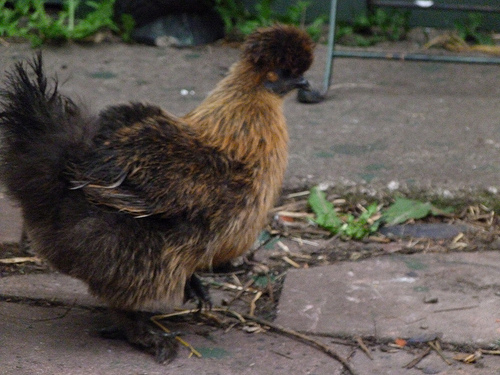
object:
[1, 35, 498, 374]
ground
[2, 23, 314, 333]
chicken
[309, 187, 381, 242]
leaf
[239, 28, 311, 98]
head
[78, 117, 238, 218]
wing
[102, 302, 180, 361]
foot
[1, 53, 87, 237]
tail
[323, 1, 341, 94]
pole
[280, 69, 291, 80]
eye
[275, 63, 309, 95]
face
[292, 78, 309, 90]
bill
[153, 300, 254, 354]
straw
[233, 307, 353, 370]
branch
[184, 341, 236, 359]
paint spot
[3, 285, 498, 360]
crack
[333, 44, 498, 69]
bar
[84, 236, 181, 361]
leg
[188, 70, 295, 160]
neck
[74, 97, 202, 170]
back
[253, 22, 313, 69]
top knot